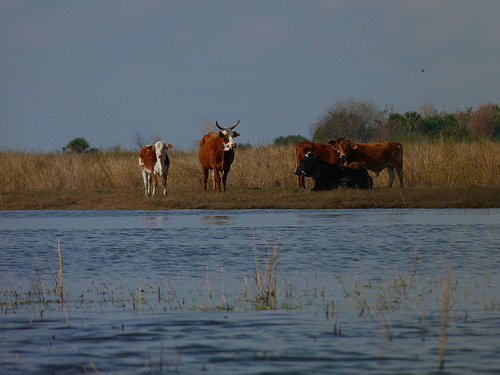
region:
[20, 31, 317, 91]
Sky is blue color.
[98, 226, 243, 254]
Water is blue color.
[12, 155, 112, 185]
Grass are brown color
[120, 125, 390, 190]
Cows are standing in the river bed.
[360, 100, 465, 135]
Trees are green color.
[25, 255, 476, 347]
Plants are in water.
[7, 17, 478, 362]
Day time picture.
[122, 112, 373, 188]
Cows are brown, white and black color.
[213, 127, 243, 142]
Cow has two pointed ears.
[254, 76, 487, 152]
Trees are behind the cows.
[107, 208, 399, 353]
the ocean is beautiful.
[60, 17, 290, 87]
a clear blue sky.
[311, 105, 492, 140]
the trees are dark brown and green.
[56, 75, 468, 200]
a bunch of huge cows.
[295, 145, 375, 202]
a black cow is laying on the grass.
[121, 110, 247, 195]
two cows are looking at the water.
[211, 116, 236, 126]
the cow horns are sticking up.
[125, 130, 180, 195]
a baby cow is brown and white.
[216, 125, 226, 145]
a cow has a spot around his eye.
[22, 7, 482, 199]
five cows are on the land.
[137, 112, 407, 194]
the herd of cows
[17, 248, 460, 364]
the grass sticking out of the water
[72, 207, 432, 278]
the still blue water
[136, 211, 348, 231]
the reflection in the water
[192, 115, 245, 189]
the cow with the horns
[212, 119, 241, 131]
the cow's horns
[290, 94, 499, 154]
the group of trees in the distance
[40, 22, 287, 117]
the clear blue sky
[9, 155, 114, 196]
the tall brown grass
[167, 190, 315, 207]
the grass near the cows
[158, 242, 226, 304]
the water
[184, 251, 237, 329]
the water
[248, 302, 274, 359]
the water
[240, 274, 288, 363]
the water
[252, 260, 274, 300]
the water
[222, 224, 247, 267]
the water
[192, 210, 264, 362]
the water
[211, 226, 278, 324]
the water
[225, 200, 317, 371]
the water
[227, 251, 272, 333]
the water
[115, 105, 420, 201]
a gang of cattle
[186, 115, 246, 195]
central animal has curious horns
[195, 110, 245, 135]
i think he's a young longhorn & his horns are new but am uncertain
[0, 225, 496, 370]
reeds growing from a body of placid blue water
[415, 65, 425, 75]
a small bird, a large airplane, or mid-sized ufo @ top mid-right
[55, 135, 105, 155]
one bushy tree in the left hand distance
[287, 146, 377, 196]
a much darker animal sits amid a clump of brown cows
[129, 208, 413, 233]
fragile reflections of cattle in water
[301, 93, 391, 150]
a huge dry tree directly behind cattle clump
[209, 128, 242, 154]
middle cattle figure wears decidedly intent expression